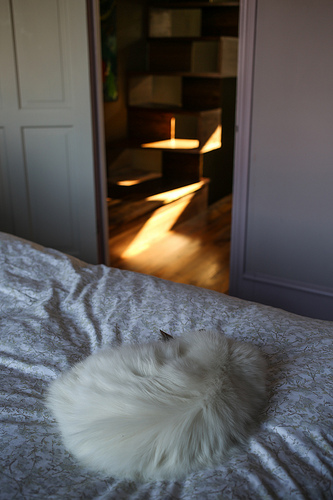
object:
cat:
[45, 328, 273, 485]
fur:
[55, 350, 261, 463]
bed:
[0, 231, 332, 500]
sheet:
[1, 232, 332, 499]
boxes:
[124, 93, 196, 147]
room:
[100, 1, 240, 294]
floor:
[108, 194, 232, 299]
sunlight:
[127, 225, 228, 289]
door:
[0, 1, 102, 264]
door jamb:
[231, 0, 255, 297]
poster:
[102, 3, 117, 102]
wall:
[100, 0, 148, 144]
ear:
[160, 330, 173, 342]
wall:
[229, 0, 332, 321]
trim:
[230, 275, 332, 324]